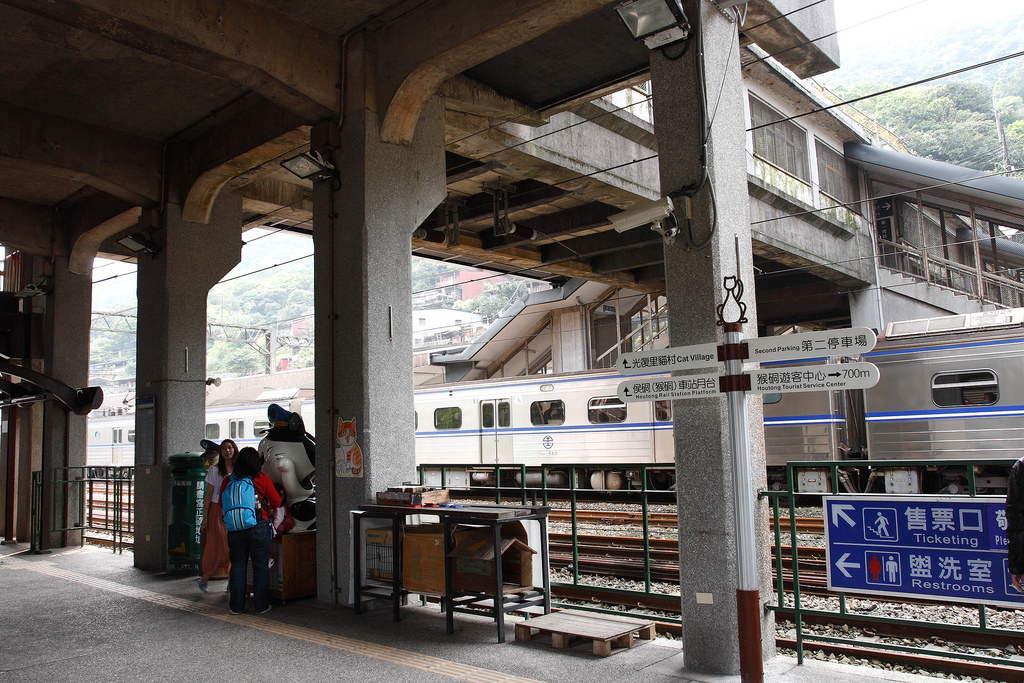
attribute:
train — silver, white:
[81, 301, 995, 466]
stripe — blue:
[94, 402, 1000, 429]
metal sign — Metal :
[714, 284, 781, 339]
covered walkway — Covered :
[721, 46, 1005, 295]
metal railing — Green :
[403, 458, 1017, 677]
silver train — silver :
[79, 325, 1015, 486]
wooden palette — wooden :
[514, 588, 646, 669]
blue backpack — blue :
[230, 471, 269, 530]